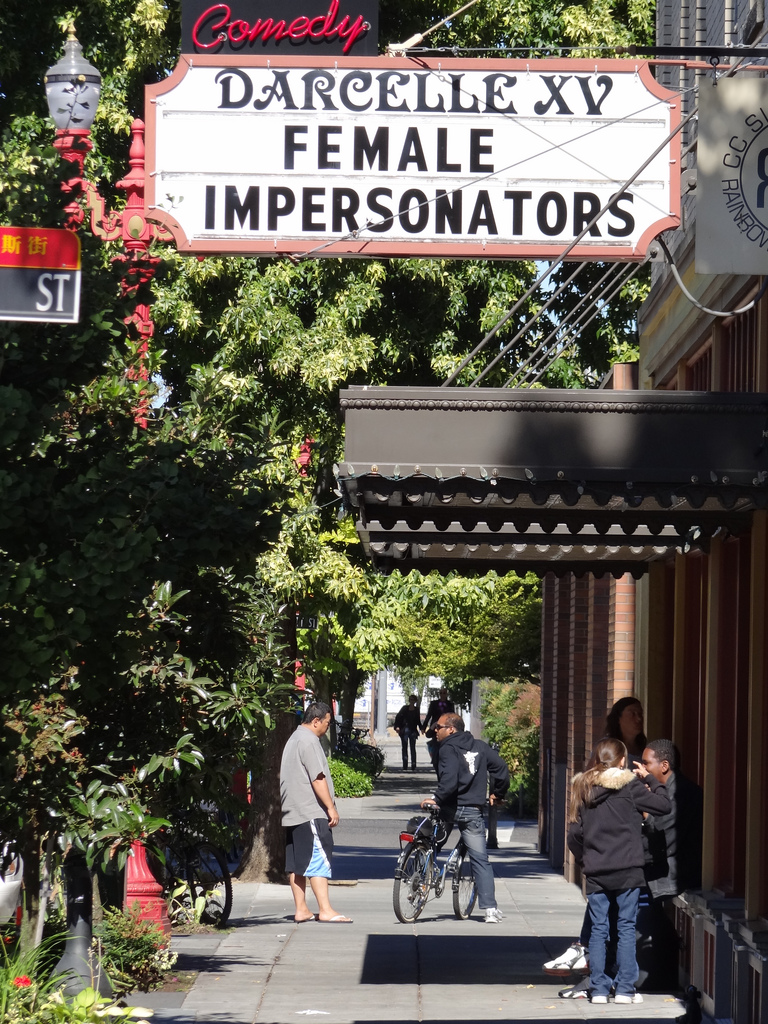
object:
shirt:
[274, 725, 346, 829]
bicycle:
[391, 789, 494, 924]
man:
[564, 732, 676, 1009]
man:
[280, 692, 354, 924]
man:
[418, 708, 516, 929]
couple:
[392, 683, 458, 770]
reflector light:
[402, 834, 412, 847]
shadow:
[366, 931, 666, 987]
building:
[544, 0, 767, 1022]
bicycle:
[157, 817, 234, 931]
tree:
[0, 2, 290, 863]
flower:
[10, 962, 36, 997]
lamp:
[36, 0, 106, 135]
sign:
[142, 50, 688, 249]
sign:
[178, 5, 381, 56]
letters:
[280, 119, 312, 172]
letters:
[394, 122, 430, 173]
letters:
[196, 178, 219, 229]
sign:
[0, 225, 74, 262]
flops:
[317, 900, 352, 925]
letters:
[36, 268, 56, 313]